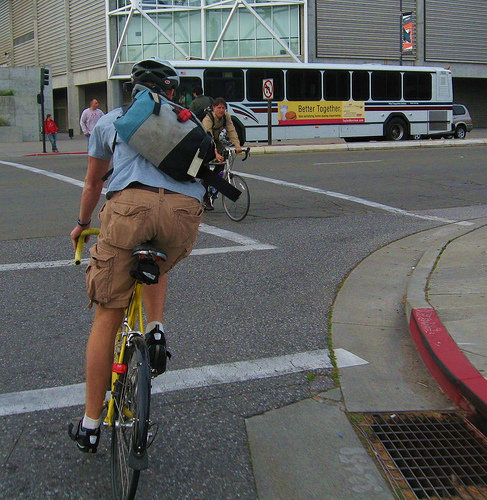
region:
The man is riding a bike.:
[73, 55, 224, 495]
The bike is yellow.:
[109, 239, 200, 466]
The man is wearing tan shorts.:
[88, 185, 209, 317]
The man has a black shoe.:
[57, 405, 111, 450]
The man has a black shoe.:
[147, 328, 185, 377]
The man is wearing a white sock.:
[145, 317, 165, 331]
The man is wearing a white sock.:
[81, 410, 104, 432]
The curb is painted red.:
[377, 291, 485, 416]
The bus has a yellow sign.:
[273, 96, 369, 127]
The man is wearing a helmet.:
[106, 46, 188, 101]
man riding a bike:
[60, 48, 189, 461]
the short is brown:
[80, 175, 194, 344]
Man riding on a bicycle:
[63, 55, 213, 497]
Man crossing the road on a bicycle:
[189, 96, 251, 221]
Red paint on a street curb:
[404, 305, 485, 414]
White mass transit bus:
[157, 57, 454, 142]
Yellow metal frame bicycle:
[72, 222, 162, 498]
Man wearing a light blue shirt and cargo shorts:
[62, 55, 204, 455]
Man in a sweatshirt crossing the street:
[77, 96, 104, 141]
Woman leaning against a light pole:
[41, 112, 61, 154]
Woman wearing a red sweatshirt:
[42, 111, 61, 154]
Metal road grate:
[342, 405, 484, 498]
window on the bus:
[399, 71, 428, 102]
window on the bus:
[366, 64, 402, 100]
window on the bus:
[351, 75, 376, 104]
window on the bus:
[324, 65, 346, 99]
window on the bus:
[282, 64, 320, 100]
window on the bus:
[247, 64, 279, 99]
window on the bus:
[203, 62, 239, 100]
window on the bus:
[176, 76, 201, 98]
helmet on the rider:
[131, 59, 183, 86]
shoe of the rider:
[49, 420, 95, 454]